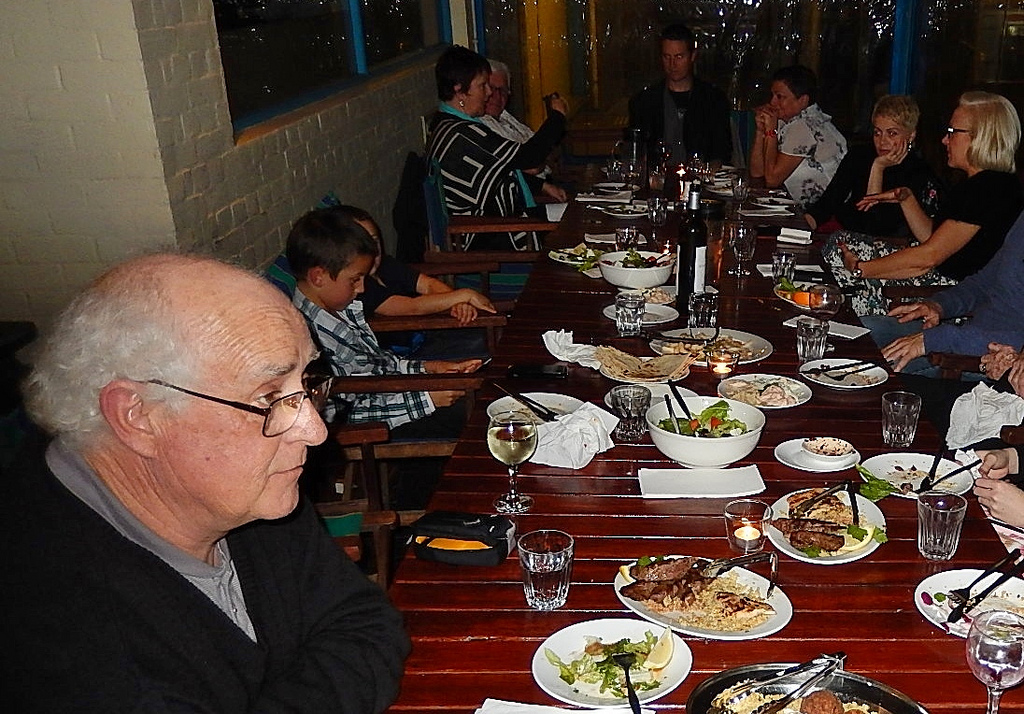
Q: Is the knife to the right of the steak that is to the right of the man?
A: Yes, the knife is to the right of the steak.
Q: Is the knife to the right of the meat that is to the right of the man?
A: Yes, the knife is to the right of the steak.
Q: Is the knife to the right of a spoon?
A: No, the knife is to the right of the steak.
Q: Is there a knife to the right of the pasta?
A: Yes, there is a knife to the right of the pasta.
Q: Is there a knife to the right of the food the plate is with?
A: Yes, there is a knife to the right of the pasta.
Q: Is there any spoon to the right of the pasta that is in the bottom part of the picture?
A: No, there is a knife to the right of the pasta.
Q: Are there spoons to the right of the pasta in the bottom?
A: No, there is a knife to the right of the pasta.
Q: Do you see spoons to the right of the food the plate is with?
A: No, there is a knife to the right of the pasta.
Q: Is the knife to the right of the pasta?
A: Yes, the knife is to the right of the pasta.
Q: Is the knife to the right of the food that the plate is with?
A: Yes, the knife is to the right of the pasta.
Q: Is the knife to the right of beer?
A: No, the knife is to the right of the pasta.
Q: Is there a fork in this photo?
A: Yes, there is a fork.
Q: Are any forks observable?
A: Yes, there is a fork.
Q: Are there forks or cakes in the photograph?
A: Yes, there is a fork.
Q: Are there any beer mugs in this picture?
A: No, there are no beer mugs.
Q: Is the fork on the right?
A: Yes, the fork is on the right of the image.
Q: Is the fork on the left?
A: No, the fork is on the right of the image.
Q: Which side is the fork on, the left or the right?
A: The fork is on the right of the image.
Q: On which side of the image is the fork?
A: The fork is on the right of the image.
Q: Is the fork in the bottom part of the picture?
A: Yes, the fork is in the bottom of the image.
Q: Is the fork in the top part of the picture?
A: No, the fork is in the bottom of the image.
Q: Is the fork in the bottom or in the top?
A: The fork is in the bottom of the image.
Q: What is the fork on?
A: The fork is on the plate.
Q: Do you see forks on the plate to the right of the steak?
A: Yes, there is a fork on the plate.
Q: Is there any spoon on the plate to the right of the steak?
A: No, there is a fork on the plate.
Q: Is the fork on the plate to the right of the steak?
A: Yes, the fork is on the plate.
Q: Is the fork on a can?
A: No, the fork is on the plate.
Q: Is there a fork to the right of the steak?
A: Yes, there is a fork to the right of the steak.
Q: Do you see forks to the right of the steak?
A: Yes, there is a fork to the right of the steak.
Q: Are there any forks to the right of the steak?
A: Yes, there is a fork to the right of the steak.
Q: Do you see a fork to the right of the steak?
A: Yes, there is a fork to the right of the steak.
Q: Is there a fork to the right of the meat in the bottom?
A: Yes, there is a fork to the right of the steak.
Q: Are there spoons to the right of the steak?
A: No, there is a fork to the right of the steak.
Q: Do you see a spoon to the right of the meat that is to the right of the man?
A: No, there is a fork to the right of the steak.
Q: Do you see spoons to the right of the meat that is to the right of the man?
A: No, there is a fork to the right of the steak.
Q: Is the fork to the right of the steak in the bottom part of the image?
A: Yes, the fork is to the right of the steak.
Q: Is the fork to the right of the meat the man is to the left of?
A: Yes, the fork is to the right of the steak.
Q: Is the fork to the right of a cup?
A: No, the fork is to the right of the steak.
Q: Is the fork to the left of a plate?
A: No, the fork is to the right of a plate.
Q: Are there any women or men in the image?
A: Yes, there is a woman.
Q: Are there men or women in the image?
A: Yes, there is a woman.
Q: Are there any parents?
A: No, there are no parents.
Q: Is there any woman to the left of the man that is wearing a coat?
A: Yes, there is a woman to the left of the man.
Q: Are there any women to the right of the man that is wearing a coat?
A: No, the woman is to the left of the man.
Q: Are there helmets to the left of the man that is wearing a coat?
A: No, there is a woman to the left of the man.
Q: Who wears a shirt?
A: The woman wears a shirt.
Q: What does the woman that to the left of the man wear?
A: The woman wears a shirt.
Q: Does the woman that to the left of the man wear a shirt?
A: Yes, the woman wears a shirt.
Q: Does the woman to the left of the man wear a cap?
A: No, the woman wears a shirt.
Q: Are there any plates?
A: Yes, there is a plate.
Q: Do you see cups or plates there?
A: Yes, there is a plate.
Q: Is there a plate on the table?
A: Yes, there is a plate on the table.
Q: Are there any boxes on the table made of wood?
A: No, there is a plate on the table.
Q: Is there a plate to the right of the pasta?
A: Yes, there is a plate to the right of the pasta.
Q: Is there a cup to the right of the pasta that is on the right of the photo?
A: No, there is a plate to the right of the pasta.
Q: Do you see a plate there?
A: Yes, there is a plate.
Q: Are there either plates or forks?
A: Yes, there is a plate.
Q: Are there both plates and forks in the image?
A: Yes, there are both a plate and a fork.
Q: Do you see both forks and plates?
A: Yes, there are both a plate and a fork.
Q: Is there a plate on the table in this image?
A: Yes, there is a plate on the table.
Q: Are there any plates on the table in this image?
A: Yes, there is a plate on the table.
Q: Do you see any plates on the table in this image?
A: Yes, there is a plate on the table.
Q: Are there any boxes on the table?
A: No, there is a plate on the table.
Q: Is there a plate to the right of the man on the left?
A: Yes, there is a plate to the right of the man.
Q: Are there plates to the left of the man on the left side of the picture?
A: No, the plate is to the right of the man.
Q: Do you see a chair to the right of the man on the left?
A: No, there is a plate to the right of the man.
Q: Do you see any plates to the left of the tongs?
A: Yes, there is a plate to the left of the tongs.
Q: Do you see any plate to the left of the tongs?
A: Yes, there is a plate to the left of the tongs.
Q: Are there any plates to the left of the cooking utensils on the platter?
A: Yes, there is a plate to the left of the tongs.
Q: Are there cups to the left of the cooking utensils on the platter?
A: No, there is a plate to the left of the tongs.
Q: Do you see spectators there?
A: No, there are no spectators.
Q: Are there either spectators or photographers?
A: No, there are no spectators or photographers.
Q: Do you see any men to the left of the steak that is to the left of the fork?
A: Yes, there is a man to the left of the steak.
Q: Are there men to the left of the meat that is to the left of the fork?
A: Yes, there is a man to the left of the steak.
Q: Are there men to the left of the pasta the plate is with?
A: Yes, there is a man to the left of the pasta.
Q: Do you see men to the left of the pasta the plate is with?
A: Yes, there is a man to the left of the pasta.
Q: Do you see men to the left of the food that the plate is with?
A: Yes, there is a man to the left of the pasta.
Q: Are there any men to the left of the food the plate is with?
A: Yes, there is a man to the left of the pasta.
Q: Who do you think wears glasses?
A: The man wears glasses.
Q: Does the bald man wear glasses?
A: Yes, the man wears glasses.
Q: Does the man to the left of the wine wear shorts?
A: No, the man wears glasses.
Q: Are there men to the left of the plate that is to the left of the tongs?
A: Yes, there is a man to the left of the plate.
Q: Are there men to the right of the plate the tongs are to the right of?
A: No, the man is to the left of the plate.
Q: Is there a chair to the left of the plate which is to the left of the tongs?
A: No, there is a man to the left of the plate.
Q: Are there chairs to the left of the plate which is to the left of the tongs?
A: No, there is a man to the left of the plate.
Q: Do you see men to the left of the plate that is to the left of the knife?
A: Yes, there is a man to the left of the plate.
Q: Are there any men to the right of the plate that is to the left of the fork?
A: No, the man is to the left of the plate.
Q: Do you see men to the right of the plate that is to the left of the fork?
A: No, the man is to the left of the plate.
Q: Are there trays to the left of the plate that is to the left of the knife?
A: No, there is a man to the left of the plate.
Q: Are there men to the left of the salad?
A: Yes, there is a man to the left of the salad.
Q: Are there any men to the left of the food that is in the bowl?
A: Yes, there is a man to the left of the salad.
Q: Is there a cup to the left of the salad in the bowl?
A: No, there is a man to the left of the salad.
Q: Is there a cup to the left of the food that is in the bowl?
A: No, there is a man to the left of the salad.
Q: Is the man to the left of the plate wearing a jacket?
A: Yes, the man is wearing a jacket.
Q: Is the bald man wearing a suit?
A: No, the man is wearing a jacket.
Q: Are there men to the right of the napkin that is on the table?
A: No, the man is to the left of the napkin.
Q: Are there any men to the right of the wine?
A: No, the man is to the left of the wine.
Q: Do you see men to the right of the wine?
A: No, the man is to the left of the wine.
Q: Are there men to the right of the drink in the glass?
A: No, the man is to the left of the wine.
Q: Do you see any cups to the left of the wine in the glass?
A: No, there is a man to the left of the wine.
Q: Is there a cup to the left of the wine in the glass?
A: No, there is a man to the left of the wine.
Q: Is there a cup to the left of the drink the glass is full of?
A: No, there is a man to the left of the wine.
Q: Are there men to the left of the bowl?
A: Yes, there is a man to the left of the bowl.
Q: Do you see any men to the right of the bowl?
A: No, the man is to the left of the bowl.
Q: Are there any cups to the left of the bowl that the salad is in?
A: No, there is a man to the left of the bowl.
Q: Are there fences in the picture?
A: No, there are no fences.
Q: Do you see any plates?
A: Yes, there is a plate.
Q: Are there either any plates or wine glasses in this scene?
A: Yes, there is a plate.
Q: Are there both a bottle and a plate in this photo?
A: Yes, there are both a plate and a bottle.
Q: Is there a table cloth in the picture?
A: No, there are no tablecloths.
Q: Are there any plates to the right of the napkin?
A: Yes, there is a plate to the right of the napkin.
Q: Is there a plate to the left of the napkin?
A: No, the plate is to the right of the napkin.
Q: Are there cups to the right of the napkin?
A: No, there is a plate to the right of the napkin.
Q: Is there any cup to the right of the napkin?
A: No, there is a plate to the right of the napkin.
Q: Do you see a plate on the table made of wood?
A: Yes, there is a plate on the table.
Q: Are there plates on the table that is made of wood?
A: Yes, there is a plate on the table.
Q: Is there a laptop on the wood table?
A: No, there is a plate on the table.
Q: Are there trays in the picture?
A: No, there are no trays.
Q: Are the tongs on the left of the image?
A: No, the tongs are on the right of the image.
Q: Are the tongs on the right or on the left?
A: The tongs are on the right of the image.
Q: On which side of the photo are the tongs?
A: The tongs are on the right of the image.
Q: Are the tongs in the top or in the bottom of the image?
A: The tongs are in the bottom of the image.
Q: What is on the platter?
A: The tongs are on the platter.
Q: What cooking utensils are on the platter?
A: The cooking utensils are tongs.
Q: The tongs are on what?
A: The tongs are on the platter.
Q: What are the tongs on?
A: The tongs are on the platter.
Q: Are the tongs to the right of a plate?
A: Yes, the tongs are to the right of a plate.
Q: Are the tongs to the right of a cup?
A: No, the tongs are to the right of a plate.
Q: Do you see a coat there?
A: Yes, there is a coat.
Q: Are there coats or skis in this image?
A: Yes, there is a coat.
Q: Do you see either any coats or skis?
A: Yes, there is a coat.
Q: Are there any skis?
A: No, there are no skis.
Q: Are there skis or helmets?
A: No, there are no skis or helmets.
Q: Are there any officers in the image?
A: No, there are no officers.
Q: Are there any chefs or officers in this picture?
A: No, there are no officers or chefs.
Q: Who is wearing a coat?
A: The man is wearing a coat.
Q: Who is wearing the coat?
A: The man is wearing a coat.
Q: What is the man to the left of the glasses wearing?
A: The man is wearing a coat.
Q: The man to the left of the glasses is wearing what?
A: The man is wearing a coat.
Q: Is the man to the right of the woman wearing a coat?
A: Yes, the man is wearing a coat.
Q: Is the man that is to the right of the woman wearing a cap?
A: No, the man is wearing a coat.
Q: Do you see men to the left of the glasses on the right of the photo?
A: Yes, there is a man to the left of the glasses.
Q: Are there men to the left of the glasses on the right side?
A: Yes, there is a man to the left of the glasses.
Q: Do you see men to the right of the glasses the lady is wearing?
A: No, the man is to the left of the glasses.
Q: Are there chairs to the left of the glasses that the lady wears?
A: No, there is a man to the left of the glasses.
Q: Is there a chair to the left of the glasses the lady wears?
A: No, there is a man to the left of the glasses.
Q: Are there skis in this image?
A: No, there are no skis.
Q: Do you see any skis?
A: No, there are no skis.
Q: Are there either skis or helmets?
A: No, there are no skis or helmets.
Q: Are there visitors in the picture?
A: No, there are no visitors.